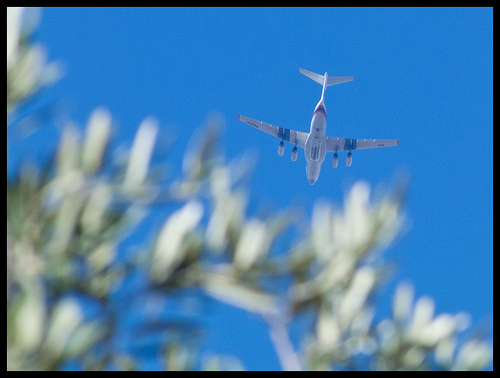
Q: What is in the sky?
A: Airplane.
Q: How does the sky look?
A: Clear and blue.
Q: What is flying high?
A: The airplane.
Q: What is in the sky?
A: A plane.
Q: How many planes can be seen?
A: 1.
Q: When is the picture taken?
A: Daytime.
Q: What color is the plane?
A: White.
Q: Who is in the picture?
A: No one.